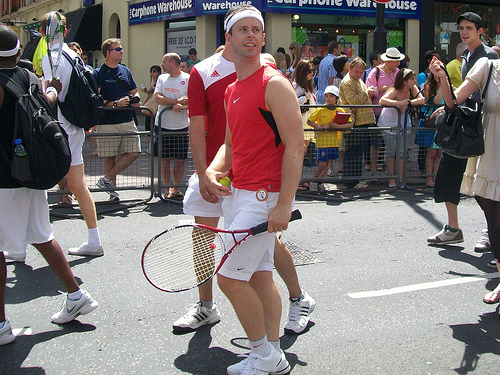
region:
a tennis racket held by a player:
[130, 197, 314, 309]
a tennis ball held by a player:
[193, 162, 245, 207]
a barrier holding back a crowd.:
[303, 92, 406, 207]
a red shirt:
[193, 51, 315, 216]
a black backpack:
[0, 70, 83, 207]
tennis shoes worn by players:
[161, 277, 325, 373]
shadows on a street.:
[429, 302, 498, 372]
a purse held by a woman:
[415, 48, 495, 172]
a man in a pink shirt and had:
[362, 45, 419, 105]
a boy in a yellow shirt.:
[304, 85, 359, 186]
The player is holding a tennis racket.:
[130, 0, 312, 369]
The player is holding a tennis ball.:
[211, 173, 268, 211]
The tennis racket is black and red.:
[139, 222, 253, 285]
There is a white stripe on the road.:
[329, 276, 499, 308]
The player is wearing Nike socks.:
[238, 328, 293, 360]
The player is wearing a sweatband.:
[218, 5, 290, 41]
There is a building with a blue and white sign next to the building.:
[124, 2, 422, 47]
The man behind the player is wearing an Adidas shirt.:
[198, 55, 226, 91]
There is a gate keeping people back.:
[114, 109, 450, 179]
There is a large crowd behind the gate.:
[52, 19, 484, 127]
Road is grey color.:
[332, 203, 407, 274]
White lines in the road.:
[340, 246, 421, 313]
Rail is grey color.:
[328, 95, 469, 203]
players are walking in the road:
[43, 72, 444, 313]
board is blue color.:
[128, 0, 259, 30]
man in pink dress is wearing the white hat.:
[370, 46, 402, 87]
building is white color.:
[120, 18, 162, 65]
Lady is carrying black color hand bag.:
[420, 46, 495, 171]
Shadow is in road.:
[27, 220, 489, 363]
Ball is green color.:
[204, 166, 241, 196]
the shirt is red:
[215, 75, 307, 236]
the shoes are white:
[210, 311, 295, 373]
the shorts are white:
[217, 179, 289, 309]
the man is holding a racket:
[133, 22, 329, 308]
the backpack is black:
[2, 24, 92, 244]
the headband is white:
[222, 7, 279, 54]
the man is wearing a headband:
[216, 7, 290, 79]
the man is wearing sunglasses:
[104, 41, 135, 64]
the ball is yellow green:
[207, 176, 240, 193]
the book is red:
[328, 107, 355, 134]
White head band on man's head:
[209, 17, 288, 39]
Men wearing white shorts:
[162, 161, 322, 301]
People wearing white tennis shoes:
[0, 265, 327, 359]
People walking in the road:
[9, 45, 474, 294]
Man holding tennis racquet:
[145, 193, 353, 285]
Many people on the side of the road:
[47, 40, 438, 136]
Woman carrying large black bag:
[418, 34, 498, 204]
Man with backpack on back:
[7, 69, 87, 204]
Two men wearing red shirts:
[166, 68, 322, 175]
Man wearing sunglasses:
[91, 40, 136, 69]